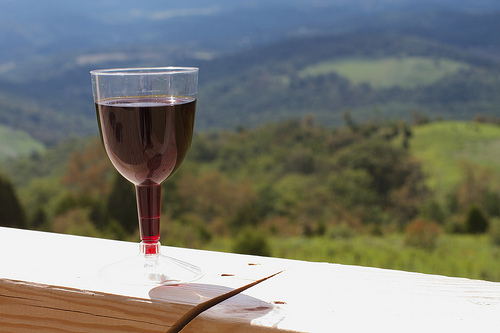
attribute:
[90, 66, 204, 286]
glass — plastic, full, white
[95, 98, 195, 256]
wine — red, black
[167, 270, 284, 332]
crack — long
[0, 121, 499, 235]
hill — green